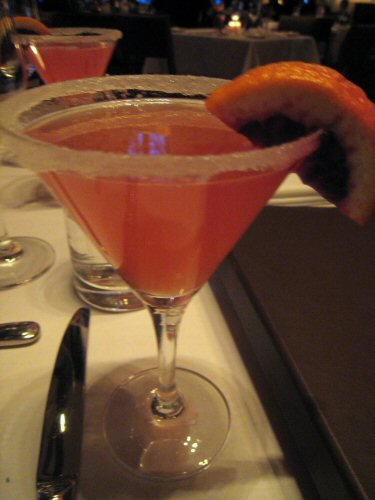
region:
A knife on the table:
[35, 307, 90, 498]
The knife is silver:
[35, 308, 90, 499]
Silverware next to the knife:
[0, 316, 41, 347]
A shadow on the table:
[80, 355, 262, 498]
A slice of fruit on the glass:
[211, 64, 373, 224]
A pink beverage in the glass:
[27, 107, 296, 296]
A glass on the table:
[2, 74, 374, 483]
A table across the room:
[173, 24, 317, 77]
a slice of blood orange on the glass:
[202, 59, 371, 219]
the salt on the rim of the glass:
[1, 70, 326, 171]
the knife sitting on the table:
[34, 305, 89, 498]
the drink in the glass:
[29, 100, 309, 296]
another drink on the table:
[15, 22, 124, 80]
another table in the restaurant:
[172, 21, 324, 81]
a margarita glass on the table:
[0, 74, 324, 480]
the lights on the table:
[226, 11, 243, 30]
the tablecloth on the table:
[141, 28, 316, 76]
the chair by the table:
[98, 14, 175, 75]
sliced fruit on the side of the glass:
[203, 60, 374, 221]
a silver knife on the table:
[37, 304, 89, 497]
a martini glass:
[0, 76, 319, 477]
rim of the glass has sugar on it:
[0, 73, 319, 179]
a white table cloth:
[0, 168, 295, 496]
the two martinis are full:
[4, 16, 347, 326]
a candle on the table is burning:
[227, 14, 240, 32]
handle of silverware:
[0, 319, 38, 348]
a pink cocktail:
[21, 101, 303, 294]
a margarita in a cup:
[33, 58, 358, 336]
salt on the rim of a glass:
[41, 127, 241, 283]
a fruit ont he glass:
[222, 48, 337, 194]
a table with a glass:
[108, 284, 244, 490]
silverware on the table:
[22, 305, 93, 489]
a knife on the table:
[7, 354, 100, 482]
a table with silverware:
[9, 310, 99, 493]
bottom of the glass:
[95, 365, 221, 478]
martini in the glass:
[38, 20, 110, 73]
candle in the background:
[213, 0, 245, 35]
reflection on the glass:
[177, 423, 203, 451]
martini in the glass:
[131, 191, 203, 237]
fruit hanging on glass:
[214, 52, 373, 230]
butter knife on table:
[38, 303, 99, 496]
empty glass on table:
[58, 197, 151, 314]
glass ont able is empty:
[62, 210, 151, 318]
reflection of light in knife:
[54, 410, 66, 432]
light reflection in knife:
[52, 410, 69, 438]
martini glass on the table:
[16, 33, 372, 490]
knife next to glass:
[33, 300, 102, 498]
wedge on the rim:
[202, 60, 372, 214]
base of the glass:
[104, 360, 237, 486]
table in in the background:
[169, 10, 303, 64]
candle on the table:
[220, 7, 248, 37]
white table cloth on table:
[162, 17, 303, 67]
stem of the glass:
[122, 298, 192, 413]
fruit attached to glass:
[203, 61, 374, 227]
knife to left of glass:
[32, 303, 94, 498]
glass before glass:
[62, 198, 145, 315]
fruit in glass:
[0, 13, 50, 37]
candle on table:
[228, 13, 240, 28]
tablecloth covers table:
[171, 19, 321, 80]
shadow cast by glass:
[76, 358, 268, 498]